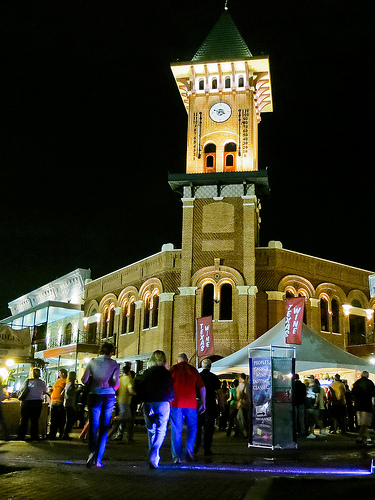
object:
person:
[82, 342, 121, 466]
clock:
[208, 102, 232, 123]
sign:
[285, 296, 305, 344]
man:
[170, 353, 206, 462]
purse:
[75, 373, 93, 409]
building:
[0, 0, 375, 371]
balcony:
[167, 170, 271, 192]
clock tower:
[168, 0, 274, 370]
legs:
[86, 397, 113, 465]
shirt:
[171, 364, 203, 409]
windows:
[201, 284, 232, 323]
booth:
[0, 324, 49, 437]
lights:
[5, 358, 15, 368]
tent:
[198, 317, 375, 374]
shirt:
[81, 357, 119, 391]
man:
[351, 371, 375, 445]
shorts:
[357, 411, 371, 426]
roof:
[191, 2, 254, 59]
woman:
[139, 350, 175, 470]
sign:
[198, 315, 214, 354]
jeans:
[169, 407, 198, 458]